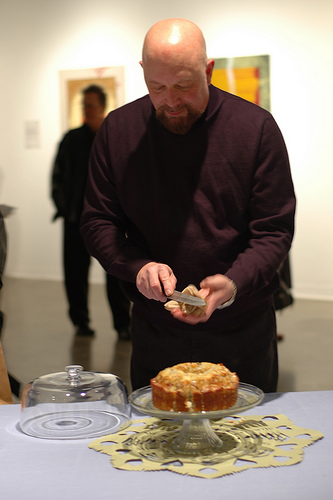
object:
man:
[76, 16, 295, 390]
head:
[138, 16, 215, 130]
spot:
[166, 20, 185, 45]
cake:
[150, 359, 238, 412]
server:
[129, 381, 265, 450]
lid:
[19, 362, 134, 441]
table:
[1, 390, 333, 500]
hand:
[136, 260, 177, 305]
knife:
[166, 287, 206, 308]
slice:
[166, 283, 206, 313]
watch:
[216, 275, 237, 309]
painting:
[68, 75, 119, 128]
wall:
[2, 1, 332, 299]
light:
[38, 20, 144, 143]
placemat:
[88, 416, 327, 481]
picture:
[213, 71, 257, 103]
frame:
[208, 54, 272, 110]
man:
[49, 77, 133, 338]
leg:
[61, 221, 90, 332]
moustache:
[154, 104, 197, 127]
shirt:
[78, 89, 297, 309]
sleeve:
[227, 120, 297, 297]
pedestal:
[168, 421, 222, 458]